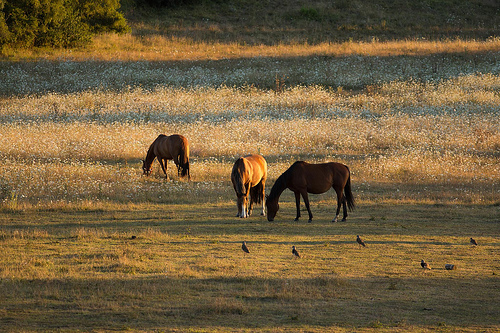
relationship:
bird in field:
[239, 239, 250, 255] [0, 211, 498, 333]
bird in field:
[286, 240, 303, 260] [0, 211, 498, 333]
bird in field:
[352, 233, 367, 248] [0, 211, 498, 333]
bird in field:
[465, 236, 480, 249] [0, 211, 498, 333]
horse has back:
[229, 150, 271, 218] [244, 154, 268, 179]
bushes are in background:
[3, 3, 124, 44] [2, 3, 496, 48]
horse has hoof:
[267, 155, 356, 225] [331, 212, 340, 222]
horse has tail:
[267, 155, 356, 225] [344, 167, 356, 216]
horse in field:
[134, 130, 192, 186] [0, 37, 498, 333]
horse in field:
[229, 150, 271, 218] [0, 37, 498, 333]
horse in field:
[267, 155, 356, 225] [0, 37, 498, 333]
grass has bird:
[1, 215, 496, 331] [239, 239, 251, 255]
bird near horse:
[239, 239, 250, 255] [137, 133, 190, 183]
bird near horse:
[286, 240, 303, 260] [137, 133, 190, 183]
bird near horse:
[352, 233, 367, 248] [137, 133, 190, 183]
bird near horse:
[465, 236, 480, 249] [137, 133, 190, 183]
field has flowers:
[3, 56, 499, 185] [0, 70, 499, 179]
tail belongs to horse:
[347, 166, 355, 209] [267, 155, 356, 225]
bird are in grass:
[239, 239, 251, 255] [1, 215, 496, 331]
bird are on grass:
[239, 239, 251, 255] [1, 215, 496, 331]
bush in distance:
[3, 3, 124, 44] [2, 3, 496, 48]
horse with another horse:
[229, 150, 271, 218] [267, 155, 356, 225]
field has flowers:
[3, 56, 499, 185] [3, 56, 499, 185]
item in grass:
[444, 261, 458, 272] [1, 215, 496, 331]